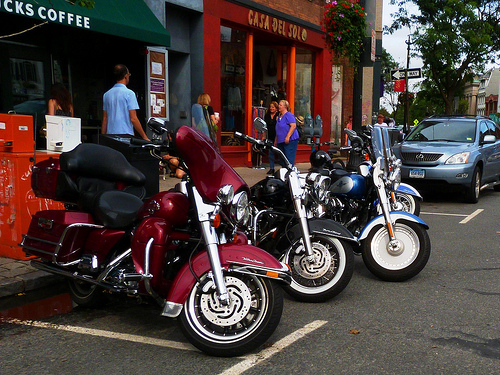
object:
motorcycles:
[19, 126, 288, 359]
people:
[273, 100, 299, 168]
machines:
[0, 114, 33, 155]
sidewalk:
[155, 158, 291, 201]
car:
[394, 114, 499, 203]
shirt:
[102, 84, 138, 137]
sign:
[390, 68, 421, 83]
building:
[191, 1, 389, 169]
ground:
[4, 227, 499, 374]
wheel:
[173, 245, 285, 358]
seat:
[60, 144, 145, 187]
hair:
[115, 66, 126, 81]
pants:
[277, 139, 297, 169]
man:
[99, 64, 148, 140]